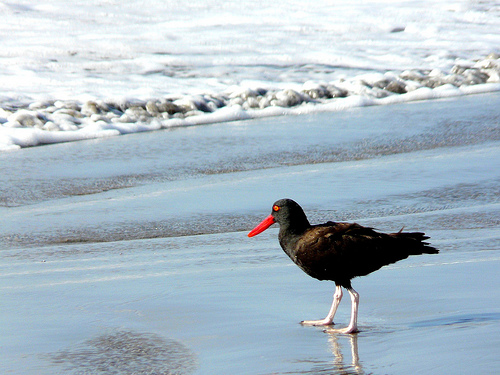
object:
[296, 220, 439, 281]
wing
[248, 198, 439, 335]
bird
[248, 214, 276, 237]
red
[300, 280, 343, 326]
birds legs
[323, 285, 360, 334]
birds legs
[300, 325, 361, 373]
reflection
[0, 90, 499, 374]
beach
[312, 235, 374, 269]
feathers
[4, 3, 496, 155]
wave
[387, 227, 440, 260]
tail feathers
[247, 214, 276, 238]
beak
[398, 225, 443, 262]
tail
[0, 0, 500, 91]
ocean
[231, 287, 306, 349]
sand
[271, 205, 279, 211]
eye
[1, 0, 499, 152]
water